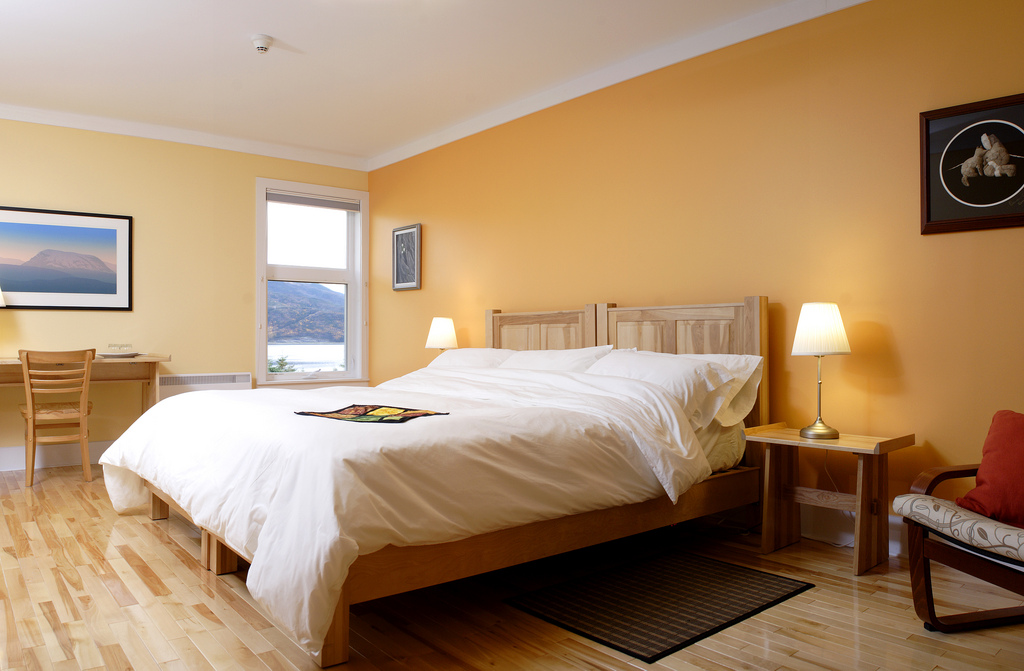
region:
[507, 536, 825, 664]
A mat on the floor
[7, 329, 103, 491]
A wooden brown chair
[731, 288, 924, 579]
A lamp on an end table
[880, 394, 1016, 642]
Red pillow on a chair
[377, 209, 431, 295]
Artwork is on the wall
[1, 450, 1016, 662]
A brown and wooden floor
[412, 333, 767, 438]
Pillows are on the bed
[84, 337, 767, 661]
White bedsheets on a bed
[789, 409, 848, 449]
The base of a lamp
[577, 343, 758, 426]
white bedroom pillow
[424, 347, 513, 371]
white bedroom pillow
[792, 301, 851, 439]
brass table lamp with white shade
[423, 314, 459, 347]
brass table lamp with white shade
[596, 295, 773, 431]
wood headboard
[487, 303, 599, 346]
wood headboard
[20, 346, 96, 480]
small wood chair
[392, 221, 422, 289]
picture with white border and frame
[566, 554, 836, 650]
small black rug on floor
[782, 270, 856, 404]
white lamp shade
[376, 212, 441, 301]
small pic on wall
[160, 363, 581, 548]
fluffy white down comforter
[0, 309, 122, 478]
wooden chair at table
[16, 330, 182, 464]
wooden table against wall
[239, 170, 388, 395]
large window in room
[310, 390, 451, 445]
design in middle of blanket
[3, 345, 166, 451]
desk against the wall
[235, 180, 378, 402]
window with view of a mountain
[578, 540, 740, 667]
rug on the floor by the bed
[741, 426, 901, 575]
wooden table by the bed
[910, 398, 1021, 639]
chair against the wall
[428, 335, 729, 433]
pillows on the bed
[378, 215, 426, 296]
small picture on the wall by the window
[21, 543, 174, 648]
hard wood plank flooring in the room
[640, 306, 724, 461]
a pillow on the bed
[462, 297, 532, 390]
a pillow on the bed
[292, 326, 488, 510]
a blanket on the bed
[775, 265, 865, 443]
a lamp on the table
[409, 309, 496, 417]
a lamp on the table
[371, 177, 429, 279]
a picture on the wall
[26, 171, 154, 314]
a picture on the wall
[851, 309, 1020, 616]
a chair in the room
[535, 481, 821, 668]
a rug under the bed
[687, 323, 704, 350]
bed frame has a wood panel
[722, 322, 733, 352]
bed frame has a wood panel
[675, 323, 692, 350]
bed frame has a wood panel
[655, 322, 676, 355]
bed frame has a wood panel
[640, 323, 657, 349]
bed frame has a wood panel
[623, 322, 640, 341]
bed frame has a wood panel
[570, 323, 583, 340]
bed frame has a wood panel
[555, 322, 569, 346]
bed frame has a wood panel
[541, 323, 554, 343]
bed frame has a wood panel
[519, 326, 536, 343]
bed frame has a wood panel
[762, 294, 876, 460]
Lamp on night stand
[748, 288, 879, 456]
Lamp next to bed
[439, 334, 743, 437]
Pillows on the bed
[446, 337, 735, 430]
White pillows on the bed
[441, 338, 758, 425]
White pillows on white bed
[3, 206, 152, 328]
Picture on the wall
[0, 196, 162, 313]
Picture above the desk